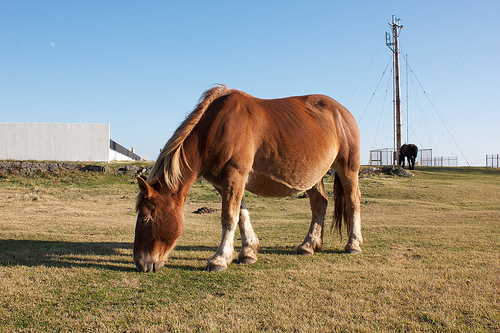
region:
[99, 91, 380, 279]
a mule in a field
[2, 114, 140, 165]
a meat processing factory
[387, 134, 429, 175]
a wild cow grazing in a field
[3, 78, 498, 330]
a field with a horse eating in it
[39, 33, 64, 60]
a small sliver of the moon in the day sky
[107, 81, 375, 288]
a mule living on a grassy farm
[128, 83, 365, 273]
a brown horse in a field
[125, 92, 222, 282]
a horse with its head down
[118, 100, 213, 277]
a horse grazing in a field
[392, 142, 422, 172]
a horse eating grass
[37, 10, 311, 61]
a clear blue sky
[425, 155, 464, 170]
a chain link fence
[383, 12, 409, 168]
a tall electrical pole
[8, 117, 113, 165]
a concrete building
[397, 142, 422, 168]
a black horse eating grass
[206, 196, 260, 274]
a horse with white feet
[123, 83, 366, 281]
horse grazing on grass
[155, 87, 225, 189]
blonde mane on the horse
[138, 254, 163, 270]
horse's mouth nibbling on grass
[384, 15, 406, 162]
utility pole behind the horses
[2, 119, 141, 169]
white building on the hillside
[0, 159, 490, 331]
pasture horses are grazing in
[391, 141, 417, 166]
horse next to utility pole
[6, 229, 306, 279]
shadow of the horse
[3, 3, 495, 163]
blue skies behind the horses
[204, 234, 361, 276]
hooves of the horse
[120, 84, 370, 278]
horse grazing in field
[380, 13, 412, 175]
antenna tower in field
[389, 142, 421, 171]
horse grazing by the antenna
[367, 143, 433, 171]
fence around the antenna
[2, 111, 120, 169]
large concrete wall in the field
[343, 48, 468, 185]
cable stays supporting the antenna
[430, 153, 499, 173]
fencing in the background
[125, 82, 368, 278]
horse has large belly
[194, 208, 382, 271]
horse has white legs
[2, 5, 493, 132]
sky is clear and blue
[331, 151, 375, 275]
Leg of a mule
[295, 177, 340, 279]
Leg of a mule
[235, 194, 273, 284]
Leg of a mule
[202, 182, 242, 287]
Leg of a mule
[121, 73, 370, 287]
This is a horse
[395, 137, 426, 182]
This is a horse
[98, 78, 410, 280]
Horse in a field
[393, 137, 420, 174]
Horse in a field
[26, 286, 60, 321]
Small patch of green grass